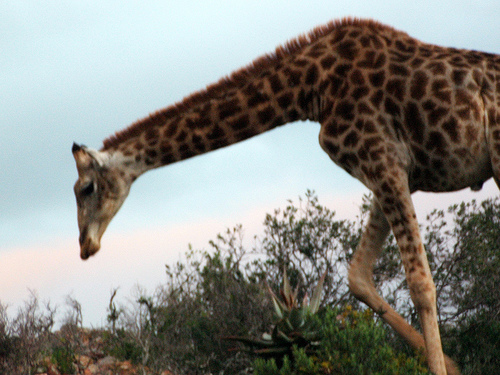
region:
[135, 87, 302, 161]
spotted pattern on long neck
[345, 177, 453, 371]
two long thin front legs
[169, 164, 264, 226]
sky is blue with clouds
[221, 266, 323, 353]
spiked plant in the background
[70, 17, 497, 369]
young giraffe with a long neck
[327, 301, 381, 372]
Plant with yellow flowers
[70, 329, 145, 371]
brown rocks in the background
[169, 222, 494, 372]
group of plants in the background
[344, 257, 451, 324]
two kneecaps of an animal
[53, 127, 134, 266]
animals head is viewed from the side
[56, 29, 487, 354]
The giraffe is brown and white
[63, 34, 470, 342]
The giraffe is walking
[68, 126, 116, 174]
The giraffe has horns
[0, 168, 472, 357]
Green trees and bushes behind giraffe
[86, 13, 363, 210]
The giraffe has a short mane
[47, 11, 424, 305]
The giraffe is lowering its head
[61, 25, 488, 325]
The giraffe has brown spots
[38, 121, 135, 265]
The giraffe's ears are perked forward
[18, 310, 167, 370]
Pile of large rocks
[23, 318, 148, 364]
Rocks are grey and tan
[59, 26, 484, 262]
the zebra is walking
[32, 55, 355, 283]
the zebras neck is bending down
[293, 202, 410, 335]
the knee is bent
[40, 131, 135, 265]
the face is light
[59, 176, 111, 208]
the eye is black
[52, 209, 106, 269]
the mouth is closed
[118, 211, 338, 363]
the leaves are dying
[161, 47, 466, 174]
the zebra has brown spots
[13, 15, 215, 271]
the sky is partly cloudy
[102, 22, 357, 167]
the zebra mane is brown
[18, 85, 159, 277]
the giraffe has ears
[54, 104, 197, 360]
the giraffe has ears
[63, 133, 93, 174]
A girraffe left ear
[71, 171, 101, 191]
A girafes left eye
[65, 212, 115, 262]
A girraffes fore face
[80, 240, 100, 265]
A giraffes lips and mouth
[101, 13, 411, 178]
A giraffes long neck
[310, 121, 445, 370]
A giraffes front legs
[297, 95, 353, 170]
A giraffes front chest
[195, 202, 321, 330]
Saharran shrubbery growing wild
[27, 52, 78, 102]
A cloudy blue sky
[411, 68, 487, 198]
A giraffes large stomach